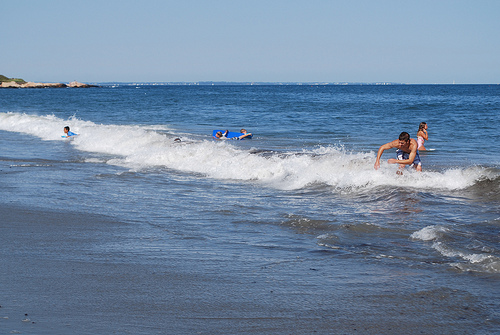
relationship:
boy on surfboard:
[214, 130, 231, 140] [211, 127, 243, 138]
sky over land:
[6, 2, 496, 94] [4, 71, 104, 94]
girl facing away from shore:
[416, 122, 428, 151] [19, 186, 158, 333]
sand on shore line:
[1, 74, 89, 89] [46, 220, 147, 278]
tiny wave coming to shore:
[409, 224, 499, 263] [138, 250, 338, 307]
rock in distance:
[8, 77, 88, 90] [8, 56, 96, 96]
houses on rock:
[63, 68, 92, 95] [6, 69, 109, 111]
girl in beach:
[416, 122, 428, 151] [1, 80, 500, 334]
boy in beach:
[373, 132, 423, 171] [1, 80, 500, 334]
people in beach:
[233, 125, 254, 143] [1, 80, 500, 334]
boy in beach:
[214, 130, 231, 140] [1, 80, 500, 334]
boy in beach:
[63, 125, 79, 136] [1, 80, 500, 334]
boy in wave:
[63, 125, 79, 136] [1, 104, 498, 204]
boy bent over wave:
[373, 132, 423, 171] [0, 116, 466, 231]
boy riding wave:
[63, 125, 79, 136] [7, 99, 497, 228]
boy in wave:
[373, 132, 423, 171] [152, 137, 365, 199]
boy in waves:
[370, 129, 424, 178] [340, 150, 402, 194]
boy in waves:
[214, 130, 231, 140] [199, 139, 350, 209]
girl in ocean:
[378, 123, 439, 155] [191, 94, 493, 278]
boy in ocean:
[373, 132, 423, 171] [3, 84, 498, 269]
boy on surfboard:
[63, 123, 78, 137] [58, 134, 73, 139]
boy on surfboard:
[217, 128, 230, 142] [212, 125, 252, 145]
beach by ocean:
[1, 128, 497, 333] [0, 83, 497, 297]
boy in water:
[373, 132, 423, 171] [265, 93, 363, 156]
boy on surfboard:
[63, 125, 79, 136] [58, 134, 65, 140]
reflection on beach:
[383, 180, 438, 214] [1, 80, 500, 334]